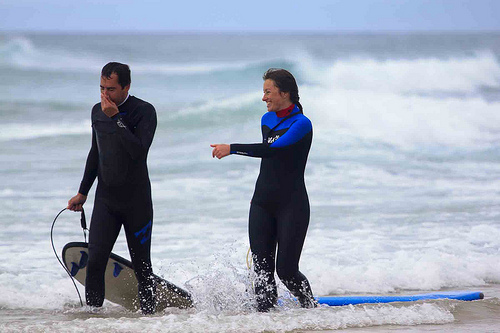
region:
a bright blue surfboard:
[273, 250, 473, 322]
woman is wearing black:
[226, 163, 319, 303]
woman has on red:
[258, 55, 290, 121]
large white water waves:
[324, 88, 469, 254]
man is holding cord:
[45, 180, 135, 246]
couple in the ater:
[42, 36, 329, 326]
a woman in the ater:
[228, 51, 410, 328]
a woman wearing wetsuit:
[222, 41, 389, 283]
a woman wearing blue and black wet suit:
[185, 58, 387, 325]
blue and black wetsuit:
[229, 51, 372, 329]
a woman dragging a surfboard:
[221, 52, 444, 307]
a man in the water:
[27, 37, 204, 327]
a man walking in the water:
[64, 58, 207, 322]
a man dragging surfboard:
[57, 53, 169, 318]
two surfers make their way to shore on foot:
[47, 55, 489, 320]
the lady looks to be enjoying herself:
[202, 62, 326, 314]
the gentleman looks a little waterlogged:
[45, 53, 202, 324]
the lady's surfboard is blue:
[268, 285, 493, 307]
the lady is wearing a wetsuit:
[207, 63, 324, 311]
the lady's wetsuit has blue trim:
[207, 63, 322, 320]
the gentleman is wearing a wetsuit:
[47, 55, 200, 323]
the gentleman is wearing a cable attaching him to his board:
[42, 191, 99, 316]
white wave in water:
[26, 266, 48, 296]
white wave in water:
[18, 237, 37, 258]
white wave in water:
[338, 245, 368, 274]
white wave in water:
[395, 226, 427, 262]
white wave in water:
[432, 253, 457, 279]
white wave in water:
[458, 245, 480, 281]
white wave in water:
[406, 227, 438, 262]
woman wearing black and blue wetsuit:
[232, 88, 352, 305]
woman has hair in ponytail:
[261, 75, 311, 139]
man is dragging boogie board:
[35, 201, 195, 331]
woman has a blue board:
[303, 278, 498, 316]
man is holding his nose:
[93, 77, 151, 132]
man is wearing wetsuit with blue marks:
[110, 199, 179, 274]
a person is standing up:
[212, 60, 317, 307]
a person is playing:
[210, 64, 323, 314]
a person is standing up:
[69, 57, 161, 314]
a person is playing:
[66, 55, 165, 310]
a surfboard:
[58, 241, 198, 317]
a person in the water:
[58, 23, 160, 290]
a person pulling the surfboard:
[181, 11, 378, 293]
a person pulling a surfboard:
[24, 20, 208, 327]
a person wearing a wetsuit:
[212, 33, 384, 330]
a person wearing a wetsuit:
[41, 58, 205, 312]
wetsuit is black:
[54, 84, 195, 279]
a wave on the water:
[334, 34, 498, 122]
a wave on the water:
[307, 55, 498, 187]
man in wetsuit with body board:
[48, 60, 193, 313]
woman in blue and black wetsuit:
[209, 69, 317, 309]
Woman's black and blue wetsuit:
[231, 108, 317, 310]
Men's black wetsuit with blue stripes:
[78, 98, 158, 311]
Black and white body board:
[51, 207, 193, 313]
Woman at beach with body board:
[210, 70, 486, 310]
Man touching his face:
[97, 61, 132, 119]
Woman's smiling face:
[261, 68, 301, 116]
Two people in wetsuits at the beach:
[49, 60, 316, 307]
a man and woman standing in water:
[77, 54, 331, 314]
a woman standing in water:
[209, 59, 316, 315]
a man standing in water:
[58, 54, 162, 316]